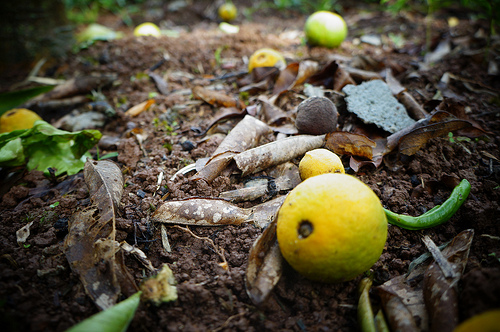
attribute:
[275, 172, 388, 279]
fruit — yellow, lemon, green, round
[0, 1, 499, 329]
ground — wet, dark, dirt, brown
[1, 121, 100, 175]
leaf — green, long, round, large, curled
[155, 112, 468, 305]
leaves — brown, long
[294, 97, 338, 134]
lemon — brown, round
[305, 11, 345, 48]
fruit — green, round, lemon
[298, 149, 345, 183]
fruit — yellow, round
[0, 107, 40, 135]
lemon — yellow, round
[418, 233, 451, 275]
stick — brown